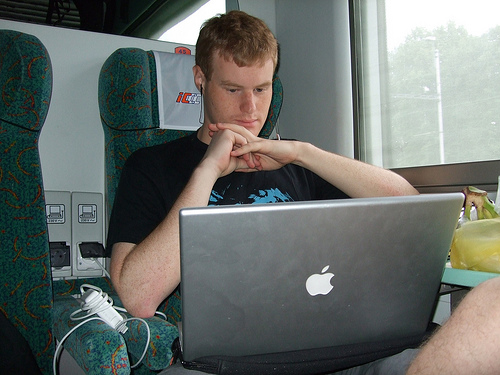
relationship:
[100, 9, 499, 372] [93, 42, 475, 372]
man sitting down in seat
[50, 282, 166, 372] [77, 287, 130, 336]
cord wrapped around charger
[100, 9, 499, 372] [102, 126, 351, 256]
man wearing shirt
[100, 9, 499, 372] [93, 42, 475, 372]
man sitting on seat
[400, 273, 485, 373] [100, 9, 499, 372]
leg belonging to man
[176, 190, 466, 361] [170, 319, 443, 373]
laptop sitting on top of laptop case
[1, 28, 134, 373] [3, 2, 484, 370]
seat sitting inside bus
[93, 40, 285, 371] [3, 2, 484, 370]
seat sitting inside bus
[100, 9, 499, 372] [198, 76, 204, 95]
man wearing earbud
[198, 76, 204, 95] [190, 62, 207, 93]
earbud placed in ear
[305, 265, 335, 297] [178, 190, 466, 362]
apple logo printed on back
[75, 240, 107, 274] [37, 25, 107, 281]
port mounted in middle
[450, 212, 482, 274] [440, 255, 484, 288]
container sitting on top of counter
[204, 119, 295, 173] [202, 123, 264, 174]
hand crossing hand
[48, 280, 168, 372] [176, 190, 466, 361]
charging cord lying next to laptop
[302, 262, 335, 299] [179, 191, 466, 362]
apple logo printed on laptop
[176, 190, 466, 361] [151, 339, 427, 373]
laptop sitting in lap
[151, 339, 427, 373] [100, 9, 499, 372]
lap belonging to man